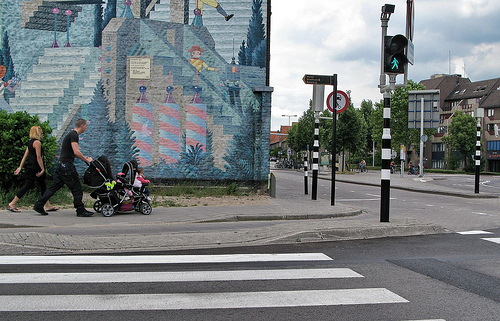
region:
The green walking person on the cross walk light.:
[390, 58, 400, 69]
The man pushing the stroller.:
[33, 107, 95, 214]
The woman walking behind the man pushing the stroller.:
[12, 122, 56, 214]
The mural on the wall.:
[0, 1, 270, 184]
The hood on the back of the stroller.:
[84, 157, 111, 188]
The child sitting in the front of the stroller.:
[137, 165, 145, 190]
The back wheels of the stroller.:
[93, 198, 117, 217]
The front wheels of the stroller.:
[134, 198, 153, 216]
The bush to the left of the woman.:
[0, 106, 51, 191]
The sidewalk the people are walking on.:
[3, 200, 355, 220]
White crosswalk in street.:
[0, 227, 491, 318]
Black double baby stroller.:
[80, 154, 158, 215]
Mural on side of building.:
[2, 1, 279, 190]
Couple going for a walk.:
[5, 114, 88, 222]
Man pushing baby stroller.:
[33, 116, 152, 221]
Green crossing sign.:
[385, 57, 403, 75]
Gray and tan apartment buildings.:
[403, 71, 494, 178]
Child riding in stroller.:
[82, 154, 152, 217]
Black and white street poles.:
[299, 95, 485, 222]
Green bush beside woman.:
[0, 110, 57, 202]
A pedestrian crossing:
[118, 257, 244, 308]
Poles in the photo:
[307, 131, 407, 218]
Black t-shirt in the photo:
[51, 128, 77, 166]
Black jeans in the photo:
[37, 166, 82, 206]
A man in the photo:
[30, 117, 86, 209]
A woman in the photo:
[6, 119, 48, 215]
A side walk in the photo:
[194, 199, 287, 221]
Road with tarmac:
[392, 259, 476, 300]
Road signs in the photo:
[285, 57, 362, 119]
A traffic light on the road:
[379, 11, 419, 88]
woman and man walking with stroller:
[9, 109, 160, 227]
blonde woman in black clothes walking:
[11, 118, 57, 223]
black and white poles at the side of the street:
[293, 78, 498, 212]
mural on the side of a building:
[2, 3, 268, 184]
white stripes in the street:
[1, 253, 416, 319]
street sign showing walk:
[378, 28, 410, 95]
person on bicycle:
[355, 153, 372, 178]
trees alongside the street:
[288, 87, 435, 179]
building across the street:
[408, 73, 498, 184]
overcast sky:
[272, 1, 498, 111]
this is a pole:
[355, 5, 412, 229]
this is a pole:
[321, 59, 355, 208]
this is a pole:
[299, 48, 330, 203]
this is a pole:
[285, 137, 313, 207]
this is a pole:
[441, 85, 496, 210]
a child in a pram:
[91, 148, 161, 221]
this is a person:
[38, 103, 98, 225]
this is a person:
[2, 114, 54, 217]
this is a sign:
[317, 83, 359, 118]